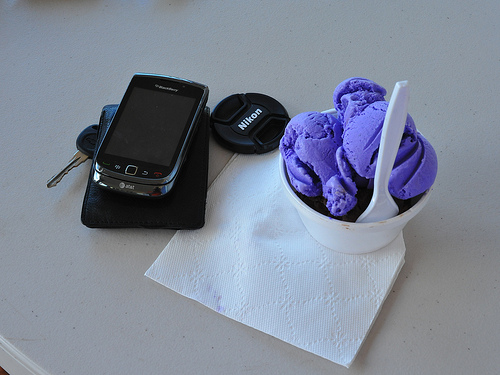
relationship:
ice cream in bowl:
[272, 75, 440, 219] [288, 169, 424, 275]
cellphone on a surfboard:
[101, 68, 208, 198] [0, 0, 500, 375]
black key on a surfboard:
[44, 123, 109, 190] [0, 0, 500, 375]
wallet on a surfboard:
[80, 95, 213, 231] [0, 0, 500, 375]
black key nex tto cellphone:
[40, 113, 97, 188] [87, 69, 213, 199]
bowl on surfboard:
[277, 107, 441, 255] [0, 0, 500, 375]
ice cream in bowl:
[278, 75, 436, 217] [277, 107, 442, 254]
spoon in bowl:
[352, 75, 421, 224] [281, 97, 428, 255]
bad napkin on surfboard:
[141, 142, 408, 370] [0, 0, 500, 375]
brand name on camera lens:
[232, 105, 267, 135] [207, 91, 294, 154]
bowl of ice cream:
[277, 107, 441, 255] [296, 103, 440, 195]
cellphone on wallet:
[87, 69, 213, 199] [80, 95, 213, 231]